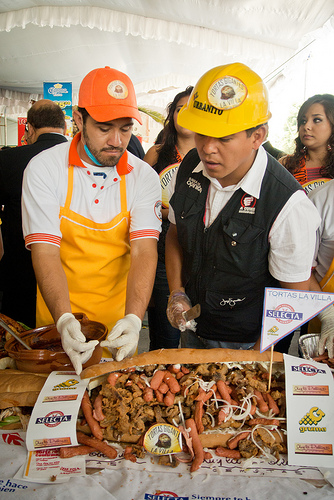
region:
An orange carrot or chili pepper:
[184, 417, 205, 473]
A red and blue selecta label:
[35, 411, 70, 428]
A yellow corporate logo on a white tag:
[297, 406, 327, 432]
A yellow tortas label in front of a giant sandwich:
[143, 422, 182, 455]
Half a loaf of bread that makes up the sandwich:
[79, 347, 282, 381]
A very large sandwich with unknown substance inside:
[60, 346, 288, 472]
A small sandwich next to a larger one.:
[0, 389, 41, 431]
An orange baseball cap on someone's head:
[76, 64, 143, 125]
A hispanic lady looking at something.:
[274, 94, 333, 186]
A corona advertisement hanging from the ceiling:
[42, 82, 73, 136]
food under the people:
[110, 363, 252, 434]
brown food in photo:
[112, 340, 237, 371]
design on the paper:
[282, 354, 329, 386]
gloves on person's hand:
[46, 295, 154, 382]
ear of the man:
[242, 123, 278, 154]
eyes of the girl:
[287, 106, 324, 133]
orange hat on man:
[73, 49, 165, 122]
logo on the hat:
[99, 75, 134, 108]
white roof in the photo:
[80, 8, 224, 53]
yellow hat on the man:
[161, 47, 283, 150]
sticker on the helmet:
[192, 67, 258, 116]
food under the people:
[70, 358, 274, 449]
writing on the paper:
[288, 355, 329, 386]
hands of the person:
[42, 303, 154, 366]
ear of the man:
[234, 121, 278, 157]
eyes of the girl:
[290, 105, 328, 132]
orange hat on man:
[80, 48, 153, 117]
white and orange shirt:
[32, 149, 165, 245]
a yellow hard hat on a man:
[177, 63, 273, 135]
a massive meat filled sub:
[66, 347, 330, 466]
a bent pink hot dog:
[183, 417, 200, 468]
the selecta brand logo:
[34, 407, 67, 422]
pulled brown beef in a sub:
[104, 382, 144, 435]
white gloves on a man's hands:
[55, 313, 143, 374]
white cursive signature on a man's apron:
[220, 297, 244, 307]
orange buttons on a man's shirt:
[84, 168, 120, 204]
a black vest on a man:
[171, 147, 306, 342]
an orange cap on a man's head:
[77, 64, 144, 124]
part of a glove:
[79, 339, 91, 343]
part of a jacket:
[213, 321, 220, 327]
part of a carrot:
[186, 406, 193, 417]